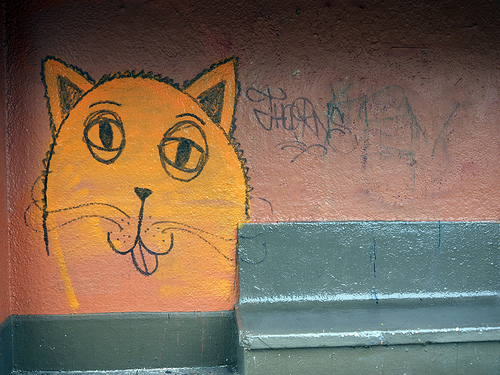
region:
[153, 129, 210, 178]
right eye on cat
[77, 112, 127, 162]
left eye on cat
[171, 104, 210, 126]
right eyebrow on cat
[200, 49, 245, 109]
right ear on cat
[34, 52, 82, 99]
left ear on cat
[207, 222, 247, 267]
cat whisker's on right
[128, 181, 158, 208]
cat nose is black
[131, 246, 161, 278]
cat tounge is out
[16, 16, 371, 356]
the wall is red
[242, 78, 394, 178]
black text graffiti on red wall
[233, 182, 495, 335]
this is a public bench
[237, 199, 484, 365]
the bench is cement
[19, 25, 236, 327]
the cat is yellow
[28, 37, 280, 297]
the cat has two ears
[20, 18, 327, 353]
yellow cat painted on red wall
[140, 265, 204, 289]
Big ship in the clear water.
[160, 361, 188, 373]
Big ship in the clear water.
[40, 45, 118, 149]
graffiti on the wall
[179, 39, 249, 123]
graffiti on the wall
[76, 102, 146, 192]
graffiti on the wall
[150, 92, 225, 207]
graffiti on the wall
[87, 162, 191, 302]
graffiti on the wall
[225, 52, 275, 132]
graffiti on the wall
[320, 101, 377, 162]
graffiti on the wall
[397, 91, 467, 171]
graffiti on the wall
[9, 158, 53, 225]
graffiti on the wall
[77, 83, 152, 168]
eye of a cat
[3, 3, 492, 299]
A wall of graffiti.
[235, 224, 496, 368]
A green bench against a wall.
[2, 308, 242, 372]
Green paint on a wall.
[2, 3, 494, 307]
Brown paint on a wall.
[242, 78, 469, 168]
Green words painted on a wall.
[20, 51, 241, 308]
A yellow cat painted on a wall.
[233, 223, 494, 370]
An empty bench.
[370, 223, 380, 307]
Blue paint streak on a bench.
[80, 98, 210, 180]
Black eyes painted on a wall.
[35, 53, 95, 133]
A cat ear painted on a brown wall.